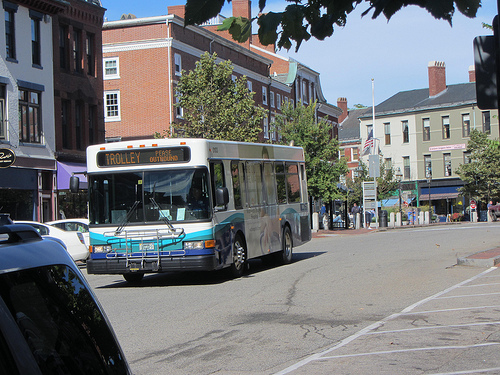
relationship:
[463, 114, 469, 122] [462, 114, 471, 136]
curtain on window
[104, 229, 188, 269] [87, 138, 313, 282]
rack on bus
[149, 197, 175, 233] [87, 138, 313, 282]
wiper on bus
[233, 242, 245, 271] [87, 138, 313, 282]
hubcap on bus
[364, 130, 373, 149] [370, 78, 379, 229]
flag on pole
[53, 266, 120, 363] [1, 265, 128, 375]
reflection on window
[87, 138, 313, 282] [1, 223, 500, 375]
bus on street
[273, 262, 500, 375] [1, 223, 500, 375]
line on street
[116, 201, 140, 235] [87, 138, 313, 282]
wiper on bus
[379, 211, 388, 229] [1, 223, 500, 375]
barrel on street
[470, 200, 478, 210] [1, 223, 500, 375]
sign on street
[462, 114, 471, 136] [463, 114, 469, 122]
window with curtain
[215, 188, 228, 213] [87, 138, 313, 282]
mirror on bus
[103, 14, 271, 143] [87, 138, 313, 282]
building behind bus